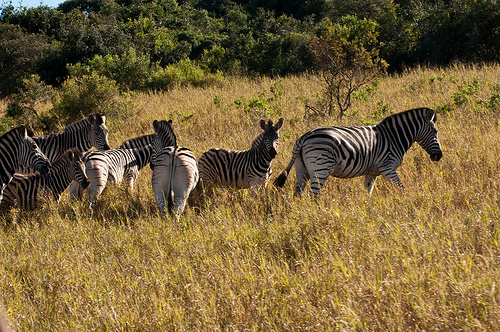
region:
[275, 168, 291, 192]
the tip of the zebras tail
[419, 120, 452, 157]
the zebras face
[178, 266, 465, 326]
yellow grass on the ground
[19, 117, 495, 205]
a whole bunch of zebras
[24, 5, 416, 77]
bushes in the background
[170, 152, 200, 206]
the rear of the zebra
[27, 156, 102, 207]
A baby zebra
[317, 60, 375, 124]
branches on a tree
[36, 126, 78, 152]
A bunch of stripes on the zebras back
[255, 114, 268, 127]
The zebras ear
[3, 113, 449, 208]
Zebras are walking.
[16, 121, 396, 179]
Zebras are black and white color.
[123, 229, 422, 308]
Grass is brown color.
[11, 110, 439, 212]
Seven zebras are in grass.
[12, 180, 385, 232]
Shadow falls on grass.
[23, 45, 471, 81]
Trees are behind the zebra.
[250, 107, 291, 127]
Zebra has two pointed ears.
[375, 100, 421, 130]
Zebra has short hairs on back.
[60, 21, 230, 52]
Trees are green color.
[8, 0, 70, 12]
Sky is blue color.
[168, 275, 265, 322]
Tall brown grass in a field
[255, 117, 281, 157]
Zebra head looking forward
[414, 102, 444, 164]
Zebra head looking right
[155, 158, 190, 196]
White back side of a zebra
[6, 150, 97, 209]
Small zebra in a herd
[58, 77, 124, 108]
Brown green plant growing in a field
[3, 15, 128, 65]
Trees growing in a field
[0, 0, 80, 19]
Blue sky above a field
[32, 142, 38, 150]
Eye of an adult zebra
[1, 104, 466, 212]
Herd of zebras in a field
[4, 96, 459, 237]
zebras in a grassy field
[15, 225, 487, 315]
brownish green grass in a field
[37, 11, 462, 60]
green bushes in the background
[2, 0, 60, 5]
blue sky in the distance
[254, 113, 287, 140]
ears of a zebra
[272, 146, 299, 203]
tail of a zebra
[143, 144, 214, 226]
back side of a zebra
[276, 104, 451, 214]
zebra walking in the grass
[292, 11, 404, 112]
tree with green leaves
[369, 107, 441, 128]
mane of a zebra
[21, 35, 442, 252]
zebras in a field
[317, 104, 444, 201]
black and white animal in field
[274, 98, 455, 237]
zebra facing the right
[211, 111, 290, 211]
zebra looking towards camera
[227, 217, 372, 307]
brown and green grass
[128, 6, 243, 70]
green trees in background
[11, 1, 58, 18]
blue sky above trees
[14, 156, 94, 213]
baby zebra in group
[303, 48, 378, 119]
branches growing out of ground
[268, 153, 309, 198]
tail of the zebra